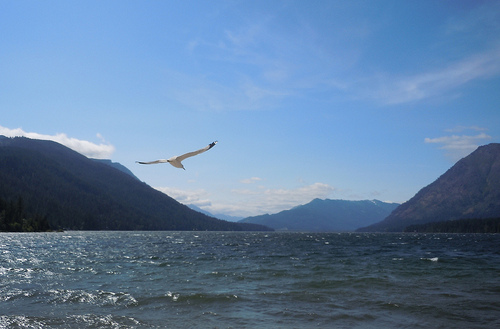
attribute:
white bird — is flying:
[128, 132, 244, 184]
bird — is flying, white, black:
[136, 141, 217, 171]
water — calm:
[265, 249, 369, 319]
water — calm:
[173, 261, 378, 327]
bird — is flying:
[143, 140, 233, 168]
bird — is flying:
[133, 136, 218, 173]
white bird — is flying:
[130, 131, 219, 183]